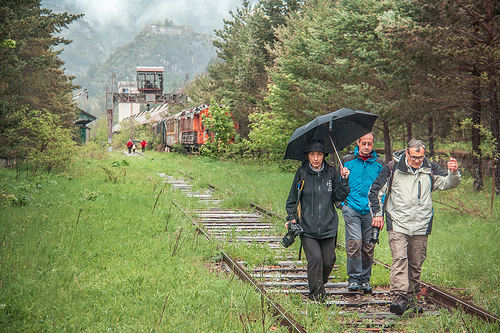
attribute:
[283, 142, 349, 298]
woman — walking, holding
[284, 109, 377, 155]
umbrella — black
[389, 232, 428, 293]
pants — brown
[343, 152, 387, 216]
jacket — blue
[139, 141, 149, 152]
person — distant, wearing red, walking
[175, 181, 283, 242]
track — abandoned, overgrown, old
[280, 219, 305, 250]
camera — digital, black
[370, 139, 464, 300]
photographer — walking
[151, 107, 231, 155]
train — old, abandoned, orange, distant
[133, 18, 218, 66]
mountain — covered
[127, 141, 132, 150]
jacket — red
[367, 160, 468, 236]
jacket — gray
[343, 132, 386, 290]
man — walking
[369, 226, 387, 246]
camera — large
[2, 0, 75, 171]
tree — green